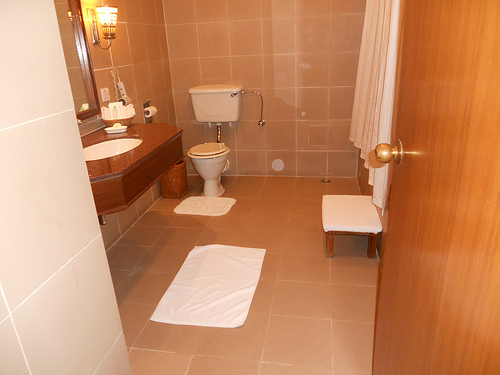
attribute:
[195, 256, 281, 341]
towel — white, full, metal, bath, water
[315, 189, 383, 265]
stool — small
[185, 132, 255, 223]
toilet — small, white, plumbing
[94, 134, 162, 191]
sink — brown, bathroom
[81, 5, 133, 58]
fixture — hanging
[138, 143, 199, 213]
trash — wicker, brown, can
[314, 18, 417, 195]
shower — white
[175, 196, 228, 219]
rug — white, throw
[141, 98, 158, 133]
paper — toilet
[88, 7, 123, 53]
light — brown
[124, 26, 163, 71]
wall — tiled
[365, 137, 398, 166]
knob — gold, door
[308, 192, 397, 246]
cover — white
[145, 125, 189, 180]
counter — brown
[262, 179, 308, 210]
tile — tan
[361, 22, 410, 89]
curtain — white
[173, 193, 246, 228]
mat — white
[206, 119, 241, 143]
pipe — metal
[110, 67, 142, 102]
box — utility